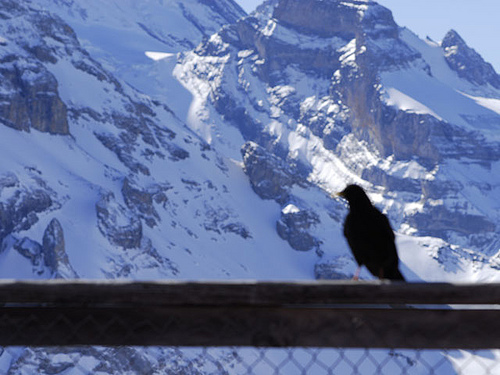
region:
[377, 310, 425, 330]
edge of a wood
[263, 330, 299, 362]
part of a meshed fence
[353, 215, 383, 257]
back of a bird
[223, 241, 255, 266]
part of some snow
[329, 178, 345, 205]
beak of a bird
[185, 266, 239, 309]
edge of a wood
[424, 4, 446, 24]
part of the sky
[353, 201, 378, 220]
neck of a bird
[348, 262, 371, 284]
leg of a bird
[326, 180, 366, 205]
the head of the bird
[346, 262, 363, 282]
the leg of a bird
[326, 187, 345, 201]
the beak of a bird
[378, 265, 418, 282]
the tail of a bird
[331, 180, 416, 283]
a bird on the ledge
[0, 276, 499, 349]
a brown wooden ledge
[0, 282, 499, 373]
a chain link fence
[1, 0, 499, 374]
a snow-covered mountain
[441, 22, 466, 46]
the peak of a mountain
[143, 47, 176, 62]
sunlight on the mountain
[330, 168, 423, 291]
Black bird.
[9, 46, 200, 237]
Shadows on the mountain.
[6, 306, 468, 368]
Wire fencing.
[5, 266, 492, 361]
Wooden support beam for the wire fencing.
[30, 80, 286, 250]
A lot of snow covering the mountain.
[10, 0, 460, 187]
Mountain in the background.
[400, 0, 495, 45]
The sky.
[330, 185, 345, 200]
The beak of the black bird.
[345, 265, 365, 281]
A leg and foot of the black bird.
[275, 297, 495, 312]
A space between the two pieces of wood.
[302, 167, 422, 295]
bird on top of railing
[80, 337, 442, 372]
open twisted wire fencing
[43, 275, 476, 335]
two long pieces of wood separating from each other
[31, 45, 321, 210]
snow covering parts of mountain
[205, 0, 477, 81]
wide circular peak on mountain top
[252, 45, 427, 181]
exposed layers of rock on mountain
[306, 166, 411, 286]
profile of bird against snowy mountain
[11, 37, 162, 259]
large jagged and smooth outcrops on mountainside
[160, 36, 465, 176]
sunlight shining directly on parts of mountain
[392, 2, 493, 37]
pale blue sky over tip of mountain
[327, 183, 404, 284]
A black bird sitting on a pole.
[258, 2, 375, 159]
A mountain covered in snow.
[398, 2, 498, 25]
A blue sky.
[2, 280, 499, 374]
A wooden and metal fence.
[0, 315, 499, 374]
Metal wire fencing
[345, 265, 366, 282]
The birds leg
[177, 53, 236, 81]
Sunlight shinning on mountain.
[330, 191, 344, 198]
The birds beak.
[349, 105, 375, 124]
Brown rock.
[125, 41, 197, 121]
The shadow of the mountain